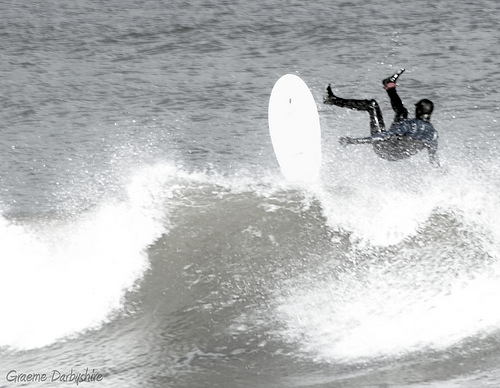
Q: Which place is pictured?
A: It is an ocean.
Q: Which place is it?
A: It is an ocean.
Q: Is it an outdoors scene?
A: Yes, it is outdoors.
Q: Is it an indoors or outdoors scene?
A: It is outdoors.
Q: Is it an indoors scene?
A: No, it is outdoors.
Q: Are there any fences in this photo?
A: No, there are no fences.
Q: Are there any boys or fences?
A: No, there are no fences or boys.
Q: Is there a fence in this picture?
A: No, there are no fences.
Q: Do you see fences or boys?
A: No, there are no fences or boys.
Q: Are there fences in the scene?
A: No, there are no fences.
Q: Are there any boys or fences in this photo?
A: No, there are no fences or boys.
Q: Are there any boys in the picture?
A: No, there are no boys.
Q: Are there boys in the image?
A: No, there are no boys.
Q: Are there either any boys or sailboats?
A: No, there are no boys or sailboats.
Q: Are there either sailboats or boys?
A: No, there are no boys or sailboats.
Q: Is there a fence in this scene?
A: No, there are no fences.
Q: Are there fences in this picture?
A: No, there are no fences.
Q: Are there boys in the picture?
A: No, there are no boys.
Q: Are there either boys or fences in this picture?
A: No, there are no boys or fences.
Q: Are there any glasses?
A: No, there are no glasses.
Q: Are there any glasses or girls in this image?
A: No, there are no glasses or girls.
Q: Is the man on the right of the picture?
A: Yes, the man is on the right of the image.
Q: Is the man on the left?
A: No, the man is on the right of the image.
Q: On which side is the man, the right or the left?
A: The man is on the right of the image.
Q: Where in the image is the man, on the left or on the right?
A: The man is on the right of the image.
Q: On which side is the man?
A: The man is on the right of the image.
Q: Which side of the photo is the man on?
A: The man is on the right of the image.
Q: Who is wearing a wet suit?
A: The man is wearing a wet suit.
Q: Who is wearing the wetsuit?
A: The man is wearing a wet suit.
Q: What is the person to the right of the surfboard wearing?
A: The man is wearing a wetsuit.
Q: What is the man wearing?
A: The man is wearing a wetsuit.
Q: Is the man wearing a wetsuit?
A: Yes, the man is wearing a wetsuit.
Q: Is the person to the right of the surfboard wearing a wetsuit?
A: Yes, the man is wearing a wetsuit.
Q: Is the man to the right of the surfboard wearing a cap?
A: No, the man is wearing a wetsuit.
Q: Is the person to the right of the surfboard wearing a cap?
A: No, the man is wearing a wetsuit.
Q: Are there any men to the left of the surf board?
A: No, the man is to the right of the surf board.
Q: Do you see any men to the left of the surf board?
A: No, the man is to the right of the surf board.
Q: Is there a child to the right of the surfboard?
A: No, there is a man to the right of the surfboard.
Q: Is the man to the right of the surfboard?
A: Yes, the man is to the right of the surfboard.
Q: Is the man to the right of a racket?
A: No, the man is to the right of the surfboard.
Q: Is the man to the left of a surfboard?
A: No, the man is to the right of a surfboard.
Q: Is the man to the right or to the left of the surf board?
A: The man is to the right of the surf board.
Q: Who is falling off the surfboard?
A: The man is falling off the surfboard.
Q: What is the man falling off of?
A: The man is falling off the surfboard.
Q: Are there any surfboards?
A: Yes, there is a surfboard.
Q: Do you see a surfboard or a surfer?
A: Yes, there is a surfboard.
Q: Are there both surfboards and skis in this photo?
A: No, there is a surfboard but no skis.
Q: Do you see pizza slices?
A: No, there are no pizza slices.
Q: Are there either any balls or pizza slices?
A: No, there are no pizza slices or balls.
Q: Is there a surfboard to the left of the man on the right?
A: Yes, there is a surfboard to the left of the man.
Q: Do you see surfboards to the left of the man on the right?
A: Yes, there is a surfboard to the left of the man.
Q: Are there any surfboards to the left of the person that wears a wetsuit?
A: Yes, there is a surfboard to the left of the man.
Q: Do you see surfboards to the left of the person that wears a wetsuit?
A: Yes, there is a surfboard to the left of the man.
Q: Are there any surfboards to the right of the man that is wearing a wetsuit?
A: No, the surfboard is to the left of the man.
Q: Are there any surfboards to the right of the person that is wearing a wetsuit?
A: No, the surfboard is to the left of the man.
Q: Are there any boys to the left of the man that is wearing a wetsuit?
A: No, there is a surfboard to the left of the man.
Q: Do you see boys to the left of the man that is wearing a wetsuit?
A: No, there is a surfboard to the left of the man.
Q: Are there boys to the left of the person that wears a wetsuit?
A: No, there is a surfboard to the left of the man.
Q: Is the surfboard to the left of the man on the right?
A: Yes, the surfboard is to the left of the man.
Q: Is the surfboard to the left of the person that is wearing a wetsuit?
A: Yes, the surfboard is to the left of the man.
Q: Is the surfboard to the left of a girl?
A: No, the surfboard is to the left of the man.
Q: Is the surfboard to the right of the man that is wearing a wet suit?
A: No, the surfboard is to the left of the man.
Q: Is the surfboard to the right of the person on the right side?
A: No, the surfboard is to the left of the man.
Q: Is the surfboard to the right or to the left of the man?
A: The surfboard is to the left of the man.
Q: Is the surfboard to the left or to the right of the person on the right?
A: The surfboard is to the left of the man.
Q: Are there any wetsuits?
A: Yes, there is a wetsuit.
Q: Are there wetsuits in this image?
A: Yes, there is a wetsuit.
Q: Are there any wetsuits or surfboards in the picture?
A: Yes, there is a wetsuit.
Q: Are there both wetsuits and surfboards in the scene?
A: Yes, there are both a wetsuit and a surfboard.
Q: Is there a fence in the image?
A: No, there are no fences.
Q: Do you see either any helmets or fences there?
A: No, there are no fences or helmets.